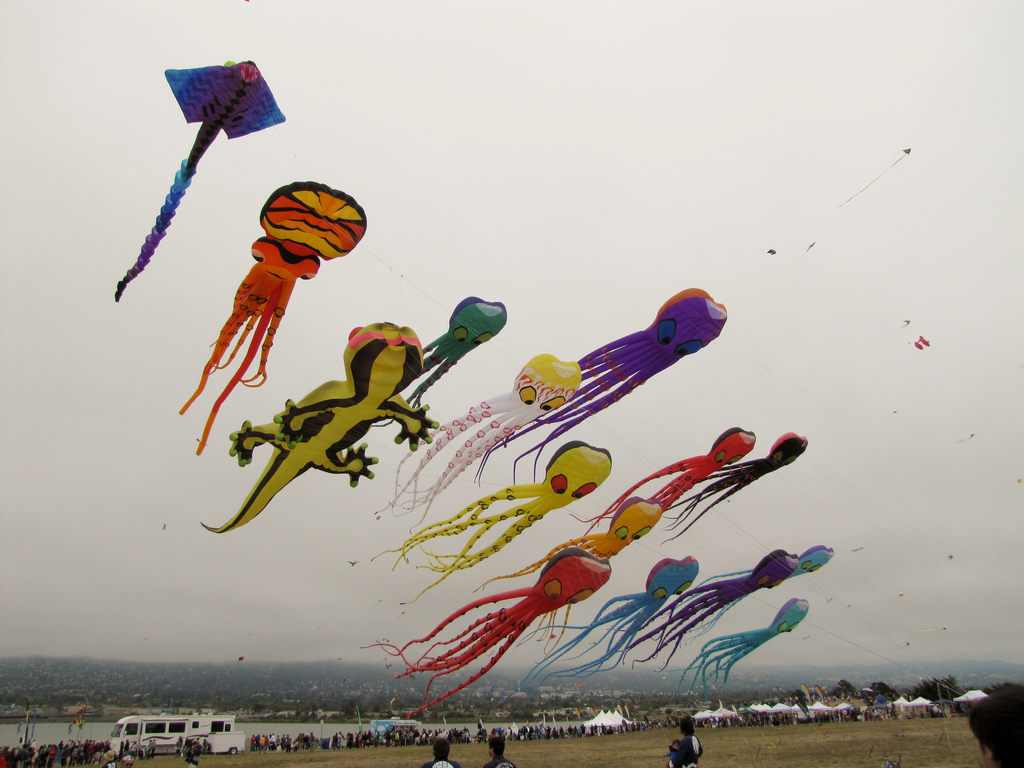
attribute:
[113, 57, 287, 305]
kite — colorful 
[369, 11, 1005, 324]
sky — gray 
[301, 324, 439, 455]
kite — shaped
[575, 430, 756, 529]
kite — Black , red 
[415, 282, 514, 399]
octopus kite — Green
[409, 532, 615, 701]
kite — in air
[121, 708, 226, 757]
rv — white 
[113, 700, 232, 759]
rv — Large 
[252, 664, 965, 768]
crowd — large